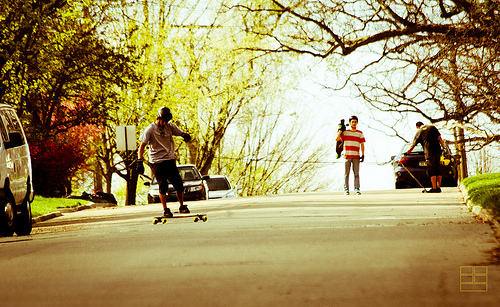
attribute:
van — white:
[1, 100, 44, 247]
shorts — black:
[143, 156, 188, 191]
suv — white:
[207, 173, 241, 200]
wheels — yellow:
[152, 216, 212, 226]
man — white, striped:
[332, 112, 367, 199]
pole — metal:
[121, 124, 136, 211]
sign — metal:
[115, 122, 139, 152]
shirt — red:
[339, 122, 366, 162]